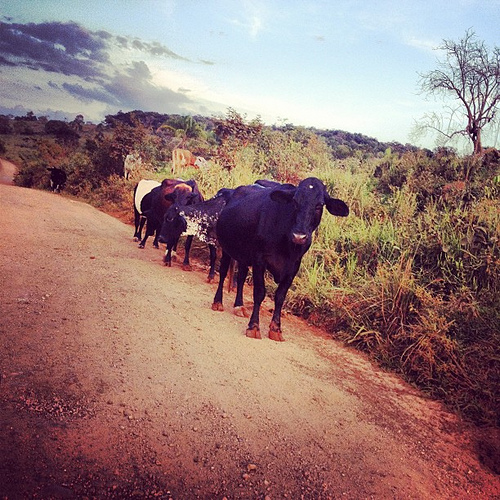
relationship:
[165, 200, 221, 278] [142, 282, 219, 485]
cow on road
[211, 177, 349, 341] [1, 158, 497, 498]
cow on road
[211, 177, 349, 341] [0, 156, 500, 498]
cow on dirt road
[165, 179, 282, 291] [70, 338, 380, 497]
cow on road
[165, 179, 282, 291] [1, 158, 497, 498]
cow on road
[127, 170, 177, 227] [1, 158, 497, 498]
cow on road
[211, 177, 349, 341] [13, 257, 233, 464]
cow on road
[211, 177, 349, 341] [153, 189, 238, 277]
cow standing before cow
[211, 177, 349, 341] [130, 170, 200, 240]
cow standing before cow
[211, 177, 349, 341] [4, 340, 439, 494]
cow on side of road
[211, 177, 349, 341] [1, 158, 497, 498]
cow on left side of road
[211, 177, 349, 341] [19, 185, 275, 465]
cow on side of road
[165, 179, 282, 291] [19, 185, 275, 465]
cow on side of road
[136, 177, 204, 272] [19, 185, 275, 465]
cow on side of road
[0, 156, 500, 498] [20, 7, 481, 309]
dirt road in country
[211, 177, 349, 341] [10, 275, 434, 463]
cow on dirt road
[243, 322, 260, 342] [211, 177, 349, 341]
hoof on cow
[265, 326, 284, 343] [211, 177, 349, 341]
hoof on cow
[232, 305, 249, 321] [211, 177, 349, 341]
hoof on cow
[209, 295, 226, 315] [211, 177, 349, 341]
hoof on cow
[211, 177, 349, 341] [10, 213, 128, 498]
cow on side of country road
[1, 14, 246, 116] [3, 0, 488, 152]
cloud in sky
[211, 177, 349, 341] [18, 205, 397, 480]
cow in road